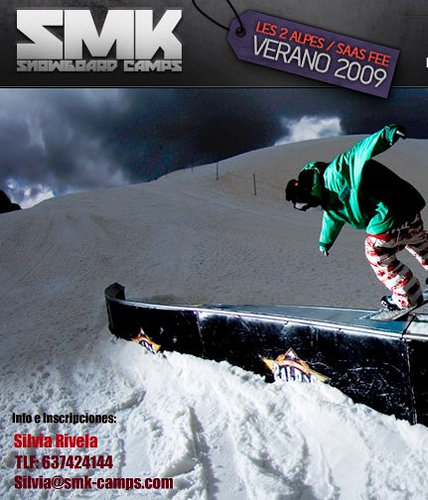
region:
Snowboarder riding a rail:
[283, 132, 425, 325]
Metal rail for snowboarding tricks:
[103, 278, 427, 430]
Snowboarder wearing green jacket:
[284, 126, 424, 256]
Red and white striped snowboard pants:
[365, 211, 426, 308]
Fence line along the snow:
[140, 152, 286, 202]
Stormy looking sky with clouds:
[0, 83, 424, 199]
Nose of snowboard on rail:
[361, 284, 426, 323]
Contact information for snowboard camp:
[8, 405, 176, 493]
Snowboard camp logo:
[15, 4, 184, 79]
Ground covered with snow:
[0, 131, 425, 498]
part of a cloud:
[184, 101, 208, 133]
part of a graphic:
[77, 408, 106, 430]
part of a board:
[360, 366, 387, 406]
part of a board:
[329, 342, 362, 427]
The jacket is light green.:
[298, 122, 427, 250]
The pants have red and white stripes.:
[364, 209, 427, 305]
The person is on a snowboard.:
[357, 284, 427, 320]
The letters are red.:
[11, 431, 174, 493]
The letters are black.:
[11, 408, 118, 429]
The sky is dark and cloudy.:
[0, 87, 426, 217]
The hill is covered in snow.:
[0, 134, 426, 498]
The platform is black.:
[104, 280, 427, 427]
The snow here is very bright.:
[103, 329, 427, 498]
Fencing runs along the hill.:
[139, 157, 287, 199]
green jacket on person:
[313, 156, 426, 242]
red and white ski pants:
[353, 233, 426, 292]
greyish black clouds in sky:
[106, 93, 224, 159]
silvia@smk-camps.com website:
[7, 467, 217, 497]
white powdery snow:
[273, 425, 392, 480]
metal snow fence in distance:
[214, 153, 285, 209]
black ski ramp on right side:
[188, 275, 409, 367]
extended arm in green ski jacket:
[336, 105, 420, 164]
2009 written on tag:
[330, 45, 394, 108]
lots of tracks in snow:
[122, 225, 297, 301]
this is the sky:
[13, 154, 69, 188]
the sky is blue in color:
[226, 107, 288, 118]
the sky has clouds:
[1, 162, 102, 187]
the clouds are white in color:
[14, 159, 78, 182]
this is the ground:
[163, 377, 225, 428]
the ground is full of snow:
[216, 384, 297, 464]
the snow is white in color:
[226, 393, 305, 461]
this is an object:
[89, 263, 421, 395]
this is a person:
[286, 128, 424, 304]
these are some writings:
[9, 407, 182, 490]